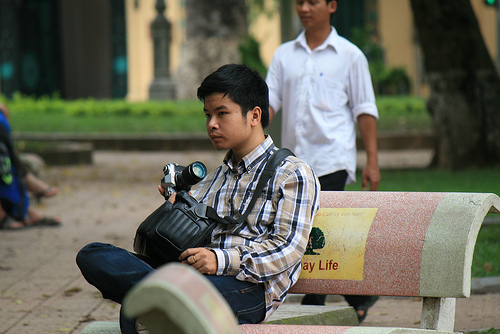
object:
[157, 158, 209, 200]
camera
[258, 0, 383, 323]
man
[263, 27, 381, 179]
shirt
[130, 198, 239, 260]
camera bag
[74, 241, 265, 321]
jeans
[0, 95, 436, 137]
grass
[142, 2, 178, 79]
statue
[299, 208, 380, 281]
stickering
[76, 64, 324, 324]
man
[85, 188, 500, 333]
bench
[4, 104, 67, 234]
woman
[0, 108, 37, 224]
dress